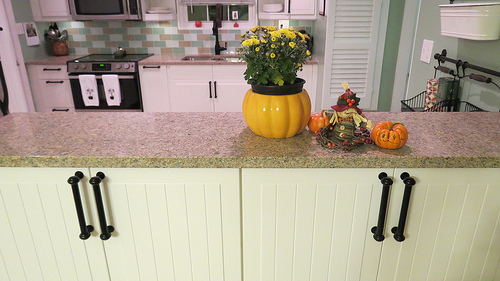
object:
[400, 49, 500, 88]
hangers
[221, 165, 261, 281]
line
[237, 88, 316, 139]
vase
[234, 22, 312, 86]
plant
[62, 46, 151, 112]
stove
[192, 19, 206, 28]
fruit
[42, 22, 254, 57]
wall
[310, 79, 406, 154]
vegetables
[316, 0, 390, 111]
door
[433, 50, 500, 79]
rod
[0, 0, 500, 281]
kitchen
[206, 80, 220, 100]
hardware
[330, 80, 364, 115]
hat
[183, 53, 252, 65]
tub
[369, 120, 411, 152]
gourd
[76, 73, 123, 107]
hand towels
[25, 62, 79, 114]
drawers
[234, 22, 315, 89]
flowers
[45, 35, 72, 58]
container